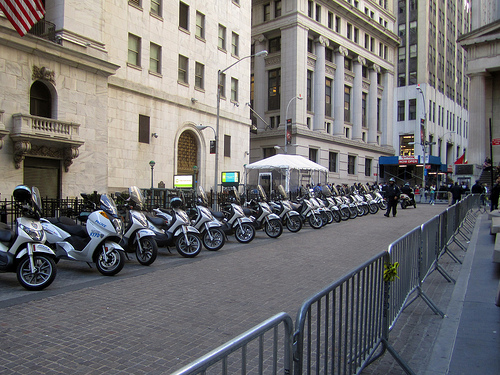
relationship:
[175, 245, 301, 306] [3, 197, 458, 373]
brick on walkway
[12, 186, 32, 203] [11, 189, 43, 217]
helmet on handlebars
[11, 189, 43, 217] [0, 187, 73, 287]
handlebars of a motorbike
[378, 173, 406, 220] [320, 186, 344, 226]
person and motorbike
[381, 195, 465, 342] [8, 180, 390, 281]
fence behind motorbikes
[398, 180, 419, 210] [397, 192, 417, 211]
person riding moped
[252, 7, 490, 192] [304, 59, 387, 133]
building has pillars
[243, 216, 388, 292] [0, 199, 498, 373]
bricks on ground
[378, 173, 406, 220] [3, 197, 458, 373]
person walking down walkway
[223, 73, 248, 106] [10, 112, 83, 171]
window with balcony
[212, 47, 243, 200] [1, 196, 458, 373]
post on sidewalk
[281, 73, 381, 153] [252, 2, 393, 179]
windows in building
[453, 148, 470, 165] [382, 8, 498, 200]
flag in distance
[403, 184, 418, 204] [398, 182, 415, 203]
person riding motorcycle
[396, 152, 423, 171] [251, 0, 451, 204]
sign on building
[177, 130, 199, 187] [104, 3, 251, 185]
doors to a building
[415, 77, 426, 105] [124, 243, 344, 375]
light for street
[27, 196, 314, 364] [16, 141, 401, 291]
row of mopeds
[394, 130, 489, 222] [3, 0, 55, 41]
portion of a flag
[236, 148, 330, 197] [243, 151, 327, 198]
mopeds behind tent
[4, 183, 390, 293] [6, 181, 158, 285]
row of motorbikes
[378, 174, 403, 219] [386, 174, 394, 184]
police man with helmet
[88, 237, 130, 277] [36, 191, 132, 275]
tire on motorcycle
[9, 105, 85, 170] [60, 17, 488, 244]
balcony on building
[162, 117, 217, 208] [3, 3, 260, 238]
entrance to building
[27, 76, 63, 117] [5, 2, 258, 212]
window of building